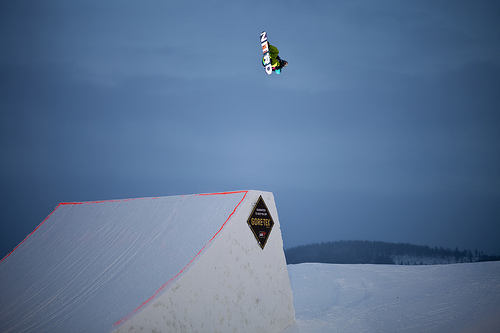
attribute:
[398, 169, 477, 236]
sky — blue 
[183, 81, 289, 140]
white clouds — white 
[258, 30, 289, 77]
snow boarder —  doing trick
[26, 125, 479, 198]
cloud — white 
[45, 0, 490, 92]
cloud — white 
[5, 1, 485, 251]
clouds — white 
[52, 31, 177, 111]
sky — blue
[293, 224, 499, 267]
trees — in the distance, in a line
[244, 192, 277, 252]
sign — black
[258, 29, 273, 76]
snowboard — painted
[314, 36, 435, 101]
clouds — white 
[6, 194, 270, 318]
square — red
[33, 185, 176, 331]
snow ramp — pink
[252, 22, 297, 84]
snowboard — completing a trick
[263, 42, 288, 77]
snowboarder — in the air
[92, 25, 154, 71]
clouds — white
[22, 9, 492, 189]
sky — blue 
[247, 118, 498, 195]
clouds — white 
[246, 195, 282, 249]
sign — black, diamond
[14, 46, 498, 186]
sky — blue 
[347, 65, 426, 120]
clouds — white 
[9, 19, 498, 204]
sky — blue 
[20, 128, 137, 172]
white clouds — white 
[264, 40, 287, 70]
snowboarder — flying 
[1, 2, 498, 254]
sky — blue 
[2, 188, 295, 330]
ramp — white, snowboarding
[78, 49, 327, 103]
clouds — white 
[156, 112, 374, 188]
clouds — white 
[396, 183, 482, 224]
clouds — white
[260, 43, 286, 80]
gear — green 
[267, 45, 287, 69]
gear — yellow